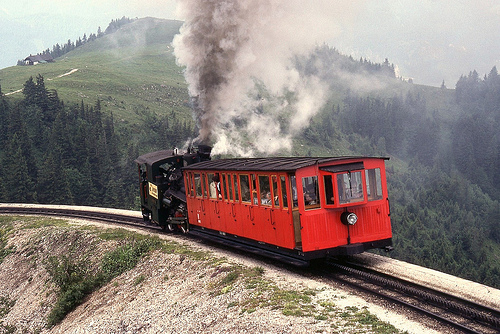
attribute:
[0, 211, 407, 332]
grass — green, brown, short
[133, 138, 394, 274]
train — red, black, passing by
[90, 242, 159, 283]
brown grass — short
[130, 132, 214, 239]
cell phone — black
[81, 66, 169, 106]
grass — brown, green, short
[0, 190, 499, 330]
track — single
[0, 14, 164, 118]
road — going up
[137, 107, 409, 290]
train — moving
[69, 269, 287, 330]
grass — short, brown, green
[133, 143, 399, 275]
grass — short, brown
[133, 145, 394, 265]
train — brown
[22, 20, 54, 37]
clouds — white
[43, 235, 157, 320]
grass — running down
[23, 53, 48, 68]
house — white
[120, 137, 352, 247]
train — red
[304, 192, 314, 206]
person — seated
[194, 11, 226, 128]
smoke — black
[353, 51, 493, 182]
sky — overcast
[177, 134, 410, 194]
roof — black